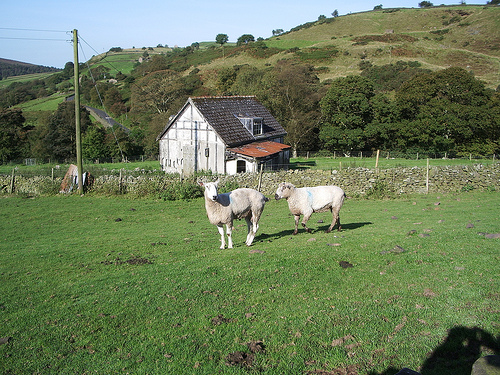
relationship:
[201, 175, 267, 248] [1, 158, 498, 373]
sheep standing on grass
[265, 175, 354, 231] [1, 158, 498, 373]
sheep on grass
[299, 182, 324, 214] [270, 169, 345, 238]
spot on sheep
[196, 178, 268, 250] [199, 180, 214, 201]
sheep has head